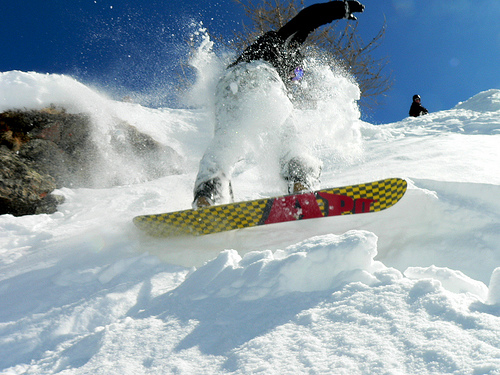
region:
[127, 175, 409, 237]
snow board with a black and gold checkerboard pattern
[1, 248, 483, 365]
white snow on a mountain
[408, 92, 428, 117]
person looking down from the mountain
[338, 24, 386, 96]
tree on the mountain above the snowboarder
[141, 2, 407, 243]
snowboarder wearing a black jacket and black gloves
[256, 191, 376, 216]
red and gray letters on the bottom of the snowboard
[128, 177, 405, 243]
view of the underside of the snowboard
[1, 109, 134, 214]
rock on the snowy mountain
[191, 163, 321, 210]
snowboarder's boots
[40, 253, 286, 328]
shadows being cast on the snow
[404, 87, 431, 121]
a person on top a hill of snow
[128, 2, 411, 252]
a person on a snowboard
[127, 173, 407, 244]
the bottom of a snowboard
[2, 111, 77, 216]
rocks sticking out of the snow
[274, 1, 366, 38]
the arm of a person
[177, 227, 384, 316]
a chunk of snow on top of the snow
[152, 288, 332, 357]
a shadow on the snow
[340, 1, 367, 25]
a black glove on a hand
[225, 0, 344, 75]
a person wearing a black winter coat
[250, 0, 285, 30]
the branches of a tree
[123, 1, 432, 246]
this person is snowboarding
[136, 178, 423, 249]
the board is yellow & black checks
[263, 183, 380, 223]
it also has red letters on it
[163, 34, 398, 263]
the snow is being slung upward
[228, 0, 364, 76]
the person is wearing a black jacket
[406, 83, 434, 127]
another person looks on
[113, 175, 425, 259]
the snow board is airborne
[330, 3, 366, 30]
the boarder is wearing gloves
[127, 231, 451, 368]
the snow appears fairly deep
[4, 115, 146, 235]
exposed rocks to the left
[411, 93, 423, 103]
the head of a man in the background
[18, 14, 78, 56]
blue skies in the background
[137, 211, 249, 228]
skiing board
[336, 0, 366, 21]
the hand of a man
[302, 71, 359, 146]
splashed snow in the air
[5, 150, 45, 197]
stones in the left side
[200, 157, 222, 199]
a leg covered in snow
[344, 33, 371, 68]
branches of a tree in the background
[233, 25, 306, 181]
a man skiing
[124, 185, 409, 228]
Person on a checked snowboard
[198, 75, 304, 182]
person wearing snow pants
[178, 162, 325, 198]
person wearing boots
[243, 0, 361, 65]
person wearing a black jacket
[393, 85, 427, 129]
person standing in the snow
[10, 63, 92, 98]
snow on a rock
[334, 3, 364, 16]
person wearing black gloves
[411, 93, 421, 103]
person wearing a helmet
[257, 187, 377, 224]
red letters on a snowboard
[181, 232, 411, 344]
snow on the ground